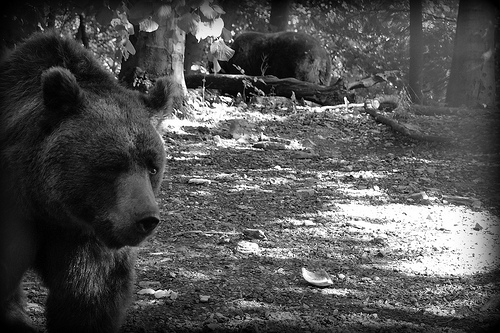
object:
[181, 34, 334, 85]
background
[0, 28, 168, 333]
bear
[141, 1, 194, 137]
trees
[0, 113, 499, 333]
ground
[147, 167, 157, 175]
eyes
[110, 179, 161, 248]
muzzle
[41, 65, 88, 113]
ear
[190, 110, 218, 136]
roots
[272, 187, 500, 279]
sunlight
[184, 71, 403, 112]
log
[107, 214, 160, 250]
snout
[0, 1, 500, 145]
forrest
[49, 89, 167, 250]
face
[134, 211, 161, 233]
nose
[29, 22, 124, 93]
back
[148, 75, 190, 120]
base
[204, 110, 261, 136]
leaves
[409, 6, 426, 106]
trunk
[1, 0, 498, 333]
picture